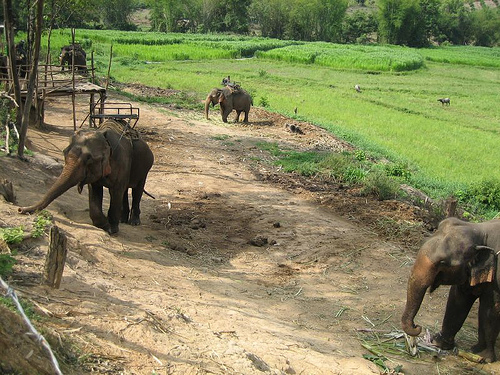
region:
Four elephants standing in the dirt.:
[13, 39, 498, 371]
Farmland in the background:
[2, 0, 498, 210]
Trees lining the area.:
[1, 2, 498, 79]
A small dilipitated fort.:
[0, 10, 106, 128]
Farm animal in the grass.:
[422, 90, 458, 111]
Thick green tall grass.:
[10, 18, 498, 98]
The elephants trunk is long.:
[15, 120, 120, 252]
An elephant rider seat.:
[64, 86, 151, 168]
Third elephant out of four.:
[195, 66, 259, 138]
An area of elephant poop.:
[124, 161, 314, 284]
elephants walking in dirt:
[0, 55, 486, 370]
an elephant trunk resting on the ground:
[20, 177, 72, 219]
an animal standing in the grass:
[425, 90, 481, 120]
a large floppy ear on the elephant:
[468, 241, 498, 293]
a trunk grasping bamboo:
[383, 300, 428, 342]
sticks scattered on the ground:
[264, 268, 350, 319]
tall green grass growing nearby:
[294, 40, 411, 70]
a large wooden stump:
[39, 214, 69, 303]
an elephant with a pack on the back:
[198, 74, 277, 119]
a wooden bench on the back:
[88, 95, 143, 125]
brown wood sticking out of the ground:
[40, 224, 71, 292]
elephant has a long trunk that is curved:
[401, 217, 490, 336]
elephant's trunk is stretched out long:
[15, 128, 93, 215]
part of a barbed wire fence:
[1, 281, 66, 373]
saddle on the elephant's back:
[87, 98, 145, 142]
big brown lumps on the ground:
[250, 218, 289, 257]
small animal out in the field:
[428, 88, 455, 111]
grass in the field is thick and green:
[281, 45, 422, 72]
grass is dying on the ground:
[364, 209, 420, 246]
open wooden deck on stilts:
[25, 67, 106, 109]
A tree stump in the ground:
[41, 223, 70, 290]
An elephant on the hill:
[203, 84, 255, 131]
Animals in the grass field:
[352, 79, 454, 110]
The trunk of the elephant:
[398, 254, 430, 336]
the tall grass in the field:
[183, 41, 425, 79]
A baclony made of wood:
[0, 34, 114, 124]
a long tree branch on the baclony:
[66, 26, 81, 131]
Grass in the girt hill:
[335, 291, 409, 374]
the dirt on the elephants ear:
[466, 269, 499, 285]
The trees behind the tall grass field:
[146, 0, 495, 40]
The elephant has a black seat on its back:
[13, 94, 160, 238]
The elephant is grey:
[37, 102, 172, 229]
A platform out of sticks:
[7, 35, 127, 138]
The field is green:
[172, 29, 488, 201]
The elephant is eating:
[376, 213, 492, 360]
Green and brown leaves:
[336, 311, 432, 369]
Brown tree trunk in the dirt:
[35, 218, 86, 290]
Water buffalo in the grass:
[428, 90, 462, 110]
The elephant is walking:
[196, 73, 269, 136]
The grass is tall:
[93, 23, 421, 70]